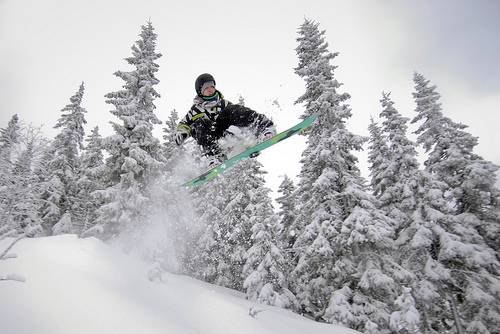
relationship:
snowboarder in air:
[172, 58, 321, 192] [1, 2, 498, 250]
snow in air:
[104, 140, 239, 274] [1, 2, 498, 250]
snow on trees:
[104, 140, 239, 274] [136, 111, 187, 267]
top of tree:
[103, 23, 171, 98] [88, 22, 168, 250]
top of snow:
[12, 230, 164, 279] [3, 236, 387, 328]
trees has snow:
[136, 111, 187, 267] [104, 140, 239, 274]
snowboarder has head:
[172, 58, 321, 192] [194, 73, 217, 98]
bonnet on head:
[194, 71, 217, 85] [194, 73, 217, 98]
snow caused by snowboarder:
[104, 140, 239, 274] [172, 58, 321, 192]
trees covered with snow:
[136, 111, 187, 267] [104, 140, 239, 274]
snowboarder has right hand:
[172, 58, 321, 192] [172, 125, 194, 145]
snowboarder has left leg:
[172, 58, 321, 192] [218, 105, 277, 141]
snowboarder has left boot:
[172, 58, 321, 192] [255, 126, 279, 139]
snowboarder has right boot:
[172, 58, 321, 192] [201, 151, 230, 167]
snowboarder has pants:
[172, 58, 321, 192] [189, 105, 283, 160]